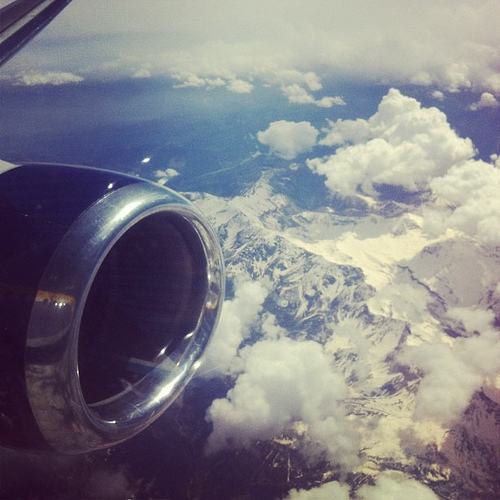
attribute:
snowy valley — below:
[262, 200, 478, 315]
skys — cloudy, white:
[107, 9, 486, 106]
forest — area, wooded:
[151, 91, 252, 152]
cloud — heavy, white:
[2, 6, 499, 105]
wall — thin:
[296, 135, 352, 165]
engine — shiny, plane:
[2, 127, 229, 467]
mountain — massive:
[226, 196, 389, 348]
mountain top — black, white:
[266, 179, 376, 337]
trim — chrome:
[19, 168, 227, 473]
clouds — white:
[245, 77, 480, 196]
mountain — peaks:
[355, 306, 498, 498]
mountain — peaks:
[192, 192, 376, 358]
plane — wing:
[11, 11, 298, 381]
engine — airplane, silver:
[2, 163, 224, 457]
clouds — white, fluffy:
[0, 3, 497, 496]